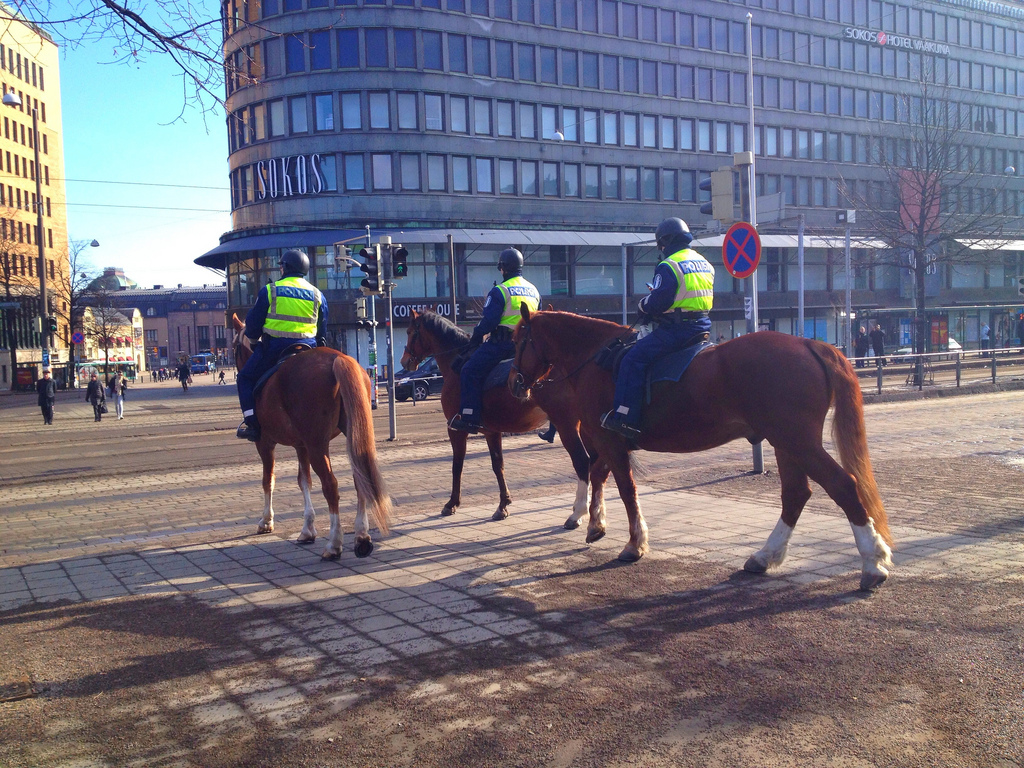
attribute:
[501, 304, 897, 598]
large horse — brown, white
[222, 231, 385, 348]
vest — yellow colored, safety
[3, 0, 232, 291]
sky — blue colored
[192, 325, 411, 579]
horse — brown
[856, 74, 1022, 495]
tree — leafless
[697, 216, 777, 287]
sign — red, blue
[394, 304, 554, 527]
horse — brown